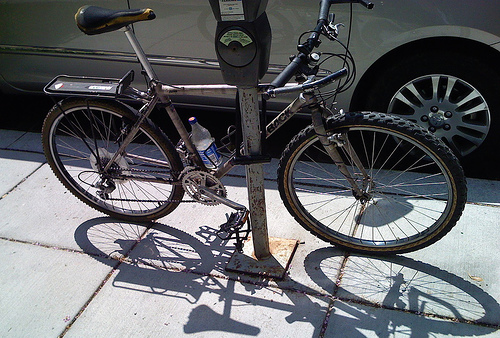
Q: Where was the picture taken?
A: It was taken at the sidewalk.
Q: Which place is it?
A: It is a sidewalk.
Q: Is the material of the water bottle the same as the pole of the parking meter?
A: No, the water bottle is made of plastic and the pole is made of metal.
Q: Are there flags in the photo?
A: No, there are no flags.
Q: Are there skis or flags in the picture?
A: No, there are no flags or skis.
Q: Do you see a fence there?
A: No, there are no fences.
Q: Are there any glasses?
A: No, there are no glasses.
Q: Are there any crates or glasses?
A: No, there are no glasses or crates.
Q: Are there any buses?
A: No, there are no buses.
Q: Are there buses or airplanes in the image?
A: No, there are no buses or airplanes.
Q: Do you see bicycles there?
A: Yes, there is a bicycle.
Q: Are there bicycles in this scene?
A: Yes, there is a bicycle.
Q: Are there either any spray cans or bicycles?
A: Yes, there is a bicycle.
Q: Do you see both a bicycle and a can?
A: No, there is a bicycle but no cans.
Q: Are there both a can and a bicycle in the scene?
A: No, there is a bicycle but no cans.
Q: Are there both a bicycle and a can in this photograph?
A: No, there is a bicycle but no cans.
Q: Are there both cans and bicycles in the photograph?
A: No, there is a bicycle but no cans.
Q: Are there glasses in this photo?
A: No, there are no glasses.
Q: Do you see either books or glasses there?
A: No, there are no glasses or books.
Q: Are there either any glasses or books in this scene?
A: No, there are no glasses or books.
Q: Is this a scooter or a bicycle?
A: This is a bicycle.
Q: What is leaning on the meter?
A: The bicycle is leaning on the meter.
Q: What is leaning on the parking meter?
A: The bicycle is leaning on the meter.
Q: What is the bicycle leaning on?
A: The bicycle is leaning on the parking meter.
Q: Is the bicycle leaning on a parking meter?
A: Yes, the bicycle is leaning on a parking meter.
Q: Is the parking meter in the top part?
A: Yes, the parking meter is in the top of the image.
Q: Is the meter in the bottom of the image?
A: No, the meter is in the top of the image.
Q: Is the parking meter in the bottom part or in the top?
A: The parking meter is in the top of the image.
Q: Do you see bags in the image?
A: No, there are no bags.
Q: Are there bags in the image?
A: No, there are no bags.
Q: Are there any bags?
A: No, there are no bags.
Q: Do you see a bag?
A: No, there are no bags.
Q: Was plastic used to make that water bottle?
A: Yes, the water bottle is made of plastic.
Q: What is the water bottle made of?
A: The water bottle is made of plastic.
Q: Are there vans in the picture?
A: No, there are no vans.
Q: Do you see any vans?
A: No, there are no vans.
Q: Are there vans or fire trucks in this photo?
A: No, there are no vans or fire trucks.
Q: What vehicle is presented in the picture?
A: The vehicle is a car.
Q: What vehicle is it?
A: The vehicle is a car.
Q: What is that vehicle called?
A: This is a car.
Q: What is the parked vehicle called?
A: The vehicle is a car.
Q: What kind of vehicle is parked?
A: The vehicle is a car.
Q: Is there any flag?
A: No, there are no flags.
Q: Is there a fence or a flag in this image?
A: No, there are no flags or fences.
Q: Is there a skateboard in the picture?
A: No, there are no skateboards.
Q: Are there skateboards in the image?
A: No, there are no skateboards.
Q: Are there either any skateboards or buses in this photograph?
A: No, there are no skateboards or buses.